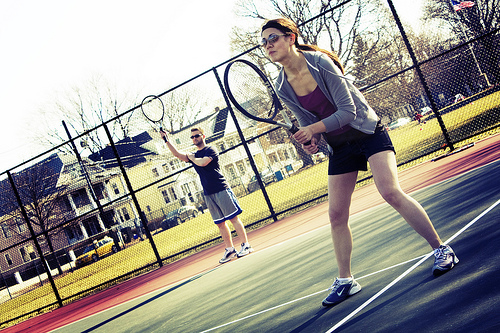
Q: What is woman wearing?
A: Sunglasses.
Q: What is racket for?
A: Tennis.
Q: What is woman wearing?
A: Shorts.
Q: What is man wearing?
A: Sunglasses.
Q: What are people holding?
A: Rackets.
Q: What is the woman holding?
A: Racket.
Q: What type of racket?
A: Tennis.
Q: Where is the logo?
A: On shoes.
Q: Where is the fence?
A: Around court.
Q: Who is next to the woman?
A: Man wearing tshirt and shorts.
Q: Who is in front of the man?
A: Woman holding a tennis racket.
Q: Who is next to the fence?
A: Man holding tennis racket.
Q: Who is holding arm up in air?
A: Man standing on tennis court.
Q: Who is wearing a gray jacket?
A: Woman standing on tennis court.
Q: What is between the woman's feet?
A: White lines on ground.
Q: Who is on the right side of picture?
A: Person wearing gray sweatshirt.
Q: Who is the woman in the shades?
A: Person holding tennis racket.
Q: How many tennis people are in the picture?
A: Two.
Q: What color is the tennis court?
A: Green.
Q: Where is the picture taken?
A: At a tennis court.